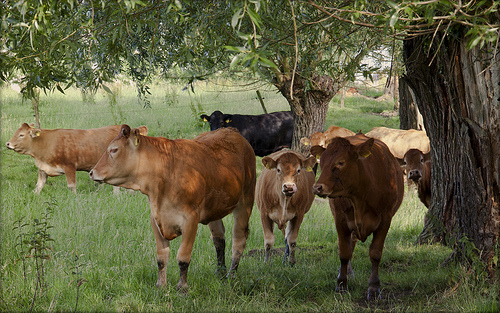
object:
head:
[399, 148, 435, 187]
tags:
[202, 118, 207, 122]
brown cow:
[307, 130, 406, 300]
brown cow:
[256, 147, 318, 267]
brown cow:
[88, 124, 257, 292]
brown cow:
[5, 119, 147, 198]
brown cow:
[394, 147, 432, 207]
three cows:
[88, 123, 405, 305]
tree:
[341, 2, 498, 272]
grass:
[41, 219, 142, 286]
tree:
[0, 0, 416, 171]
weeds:
[1, 196, 58, 311]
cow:
[299, 125, 356, 163]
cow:
[359, 125, 430, 159]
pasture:
[4, 36, 479, 290]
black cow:
[200, 110, 318, 177]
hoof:
[363, 284, 383, 301]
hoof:
[332, 273, 351, 293]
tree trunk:
[412, 40, 499, 270]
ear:
[222, 115, 234, 125]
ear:
[200, 114, 211, 123]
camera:
[187, 117, 447, 297]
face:
[89, 135, 137, 184]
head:
[305, 138, 377, 199]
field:
[0, 73, 498, 310]